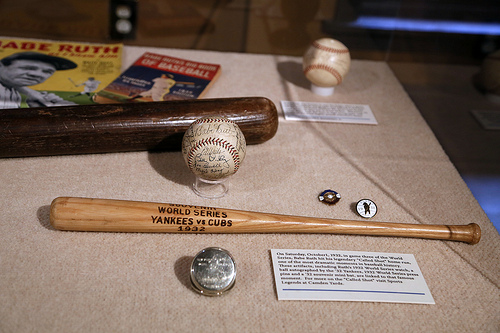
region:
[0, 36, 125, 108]
Babe Ruth on cover of a yellow magazine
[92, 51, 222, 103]
basebal book on table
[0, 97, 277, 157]
dark brown wood baseball bat on table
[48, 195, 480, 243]
wood baseball bat sitting on table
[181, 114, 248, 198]
autographed baseball on stand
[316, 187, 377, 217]
two baseball pins on a table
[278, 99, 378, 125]
white information card in display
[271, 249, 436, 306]
white information card in display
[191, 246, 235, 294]
shiny metal object in baseball display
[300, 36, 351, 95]
an autographed baseball on display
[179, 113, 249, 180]
Baseball on a table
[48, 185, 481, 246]
Bat on the table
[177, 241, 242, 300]
silver coin on the table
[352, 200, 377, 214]
white button on the table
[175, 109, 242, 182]
signed baseball between two bats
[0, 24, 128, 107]
Book about Babe Ruth on the table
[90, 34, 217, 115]
book about baseball on the table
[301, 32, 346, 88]
Baseball on display on a table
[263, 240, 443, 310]
Small card with writing on it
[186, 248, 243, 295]
silver coin on display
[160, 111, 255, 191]
baseball on a table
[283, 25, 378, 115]
baseball on a table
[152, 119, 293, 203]
old baseball on a table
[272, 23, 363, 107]
old baseball on a table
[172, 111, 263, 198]
a baseball on a table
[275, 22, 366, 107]
a baseball on a table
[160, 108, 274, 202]
white baseball on a table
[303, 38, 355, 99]
white baseball on a table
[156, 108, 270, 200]
round baseball on a table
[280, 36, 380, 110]
round baseball on a table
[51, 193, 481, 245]
A wood baseball bat.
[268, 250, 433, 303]
White and black card.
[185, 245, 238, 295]
A roung silver item.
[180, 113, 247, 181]
A baseball with writing on it.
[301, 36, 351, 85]
A round white ball.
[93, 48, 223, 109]
An old baseball book.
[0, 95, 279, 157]
A dark wood bat.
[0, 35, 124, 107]
An old baseball magazine.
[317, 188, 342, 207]
Blue white and gold pin.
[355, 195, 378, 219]
A round baseball pin.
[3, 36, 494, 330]
collection of baseball memorabilia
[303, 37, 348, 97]
ball on white base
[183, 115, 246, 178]
autographs on surface of ball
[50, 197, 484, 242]
words on wood bat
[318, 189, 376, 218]
two small round pins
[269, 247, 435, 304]
white card with words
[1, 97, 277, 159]
end of wood bat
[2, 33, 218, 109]
two books about baseball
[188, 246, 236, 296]
round silver cover with etchings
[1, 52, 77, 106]
picture on cover of book